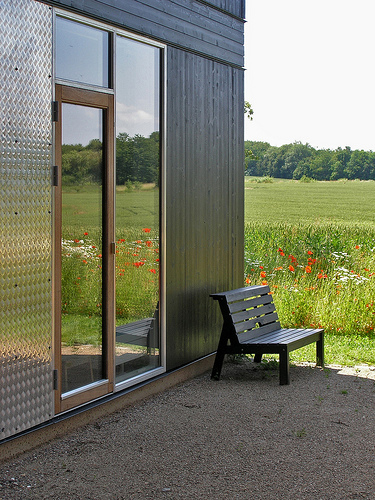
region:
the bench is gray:
[177, 247, 314, 395]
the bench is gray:
[218, 263, 336, 377]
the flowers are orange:
[274, 240, 325, 288]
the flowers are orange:
[299, 254, 347, 287]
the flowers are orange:
[248, 257, 281, 293]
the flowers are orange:
[271, 244, 347, 308]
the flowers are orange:
[306, 228, 356, 294]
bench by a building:
[206, 282, 333, 376]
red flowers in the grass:
[268, 244, 321, 271]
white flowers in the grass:
[340, 263, 369, 289]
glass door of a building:
[48, 75, 118, 409]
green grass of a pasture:
[246, 186, 367, 221]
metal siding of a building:
[6, 79, 47, 422]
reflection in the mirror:
[125, 230, 163, 343]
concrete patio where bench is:
[167, 385, 356, 477]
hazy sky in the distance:
[272, 13, 356, 119]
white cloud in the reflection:
[121, 102, 159, 133]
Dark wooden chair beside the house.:
[214, 281, 325, 384]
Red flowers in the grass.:
[243, 242, 352, 307]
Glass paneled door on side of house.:
[50, 78, 116, 411]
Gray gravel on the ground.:
[1, 348, 372, 494]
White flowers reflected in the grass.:
[61, 227, 92, 263]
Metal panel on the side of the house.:
[1, 0, 60, 445]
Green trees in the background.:
[244, 136, 373, 181]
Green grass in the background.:
[244, 173, 373, 222]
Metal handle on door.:
[109, 240, 115, 254]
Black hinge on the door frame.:
[51, 365, 57, 392]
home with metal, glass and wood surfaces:
[4, 1, 247, 454]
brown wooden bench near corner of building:
[210, 278, 321, 383]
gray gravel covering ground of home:
[1, 350, 368, 491]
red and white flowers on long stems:
[244, 240, 368, 336]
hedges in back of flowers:
[248, 211, 370, 280]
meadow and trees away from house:
[242, 136, 369, 220]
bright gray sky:
[244, 4, 368, 147]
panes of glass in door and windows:
[51, 15, 165, 410]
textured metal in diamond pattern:
[1, 0, 48, 436]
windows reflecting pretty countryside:
[55, 12, 160, 407]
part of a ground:
[216, 391, 248, 433]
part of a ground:
[203, 452, 233, 490]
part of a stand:
[276, 362, 286, 382]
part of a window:
[69, 359, 101, 389]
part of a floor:
[264, 397, 294, 432]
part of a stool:
[268, 355, 296, 381]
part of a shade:
[227, 446, 252, 492]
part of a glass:
[62, 347, 86, 384]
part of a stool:
[312, 346, 328, 378]